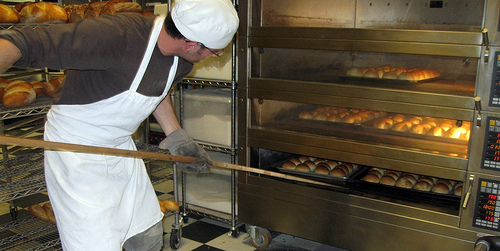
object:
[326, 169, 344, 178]
bread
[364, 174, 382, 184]
bread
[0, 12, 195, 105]
sweater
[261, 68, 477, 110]
shelf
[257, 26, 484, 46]
shelf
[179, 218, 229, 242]
tile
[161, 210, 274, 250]
floor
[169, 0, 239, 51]
hat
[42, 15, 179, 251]
white apron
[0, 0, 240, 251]
man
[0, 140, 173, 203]
rack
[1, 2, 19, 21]
bread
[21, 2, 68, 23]
bread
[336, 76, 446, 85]
pan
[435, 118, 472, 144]
light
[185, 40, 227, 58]
eyeglasses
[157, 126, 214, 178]
glove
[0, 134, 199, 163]
handle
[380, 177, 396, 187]
buns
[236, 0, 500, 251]
commercial oven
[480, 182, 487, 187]
front buttons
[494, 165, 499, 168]
front buttons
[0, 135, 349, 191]
pan handle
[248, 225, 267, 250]
wheel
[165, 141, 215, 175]
hand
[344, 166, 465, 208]
pan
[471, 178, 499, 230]
controls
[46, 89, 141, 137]
waist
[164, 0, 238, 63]
head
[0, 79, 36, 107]
bread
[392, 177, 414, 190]
bread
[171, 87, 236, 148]
box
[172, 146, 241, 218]
box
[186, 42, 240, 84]
box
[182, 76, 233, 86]
rack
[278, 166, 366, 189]
pan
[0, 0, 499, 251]
bakery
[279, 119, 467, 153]
metal rack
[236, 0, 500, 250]
stand